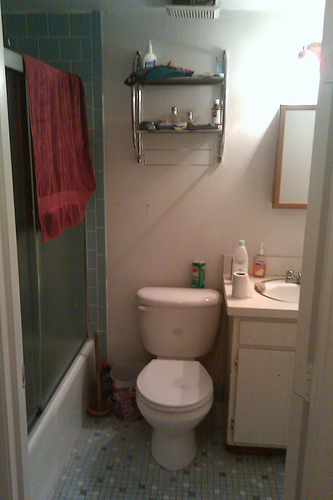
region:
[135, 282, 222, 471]
a white porcelain toilet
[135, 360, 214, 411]
a white plastic toilet seat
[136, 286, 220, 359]
a white porcelain toilet tank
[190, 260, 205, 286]
a can of Comet cleanser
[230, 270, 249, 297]
a roll of toilet paper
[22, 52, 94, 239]
a red bath towel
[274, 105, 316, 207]
a wood framed bathroom mirror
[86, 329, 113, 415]
a toilet plunger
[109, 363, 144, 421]
a bathroom waste basket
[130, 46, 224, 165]
a chrome metal shelf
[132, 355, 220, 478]
This is a toilet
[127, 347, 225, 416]
This is a toilet seat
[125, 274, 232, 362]
This is a toilet cistern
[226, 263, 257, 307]
This is a toilet paper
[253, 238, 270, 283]
This is a toilet hand wash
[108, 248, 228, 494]
This is a toilet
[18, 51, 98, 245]
red towel hanging on the shower door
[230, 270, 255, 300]
roll of toilet paper on the counter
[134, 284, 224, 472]
a white toilet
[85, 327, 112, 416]
a toilet plunger on the floor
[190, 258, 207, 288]
bottle of Comet on the back of the toilet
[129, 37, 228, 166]
set of metal shelves on the wall above the toilet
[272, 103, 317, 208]
corner of a mirror with a wood frame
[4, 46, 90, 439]
frosted glass shower door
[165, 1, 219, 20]
air conditioning vent on the ceiling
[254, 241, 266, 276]
bottle of hand soap by the sink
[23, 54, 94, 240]
a red towel on the shower door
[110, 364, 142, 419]
small round trash can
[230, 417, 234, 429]
hinge on the cabinet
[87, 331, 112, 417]
the plunger has a wooden handle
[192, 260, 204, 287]
green can of cleaning product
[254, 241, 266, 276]
bottle of hand soap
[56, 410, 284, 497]
blue tiles are square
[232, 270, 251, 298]
used roll of toilet paper on the counter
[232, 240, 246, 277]
a bottle of shampoo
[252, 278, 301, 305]
a metal lined sink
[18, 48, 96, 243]
a maroon towel hanging on shower door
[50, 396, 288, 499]
floor made of small square tiles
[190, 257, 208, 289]
a container of comet cleaner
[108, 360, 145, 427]
an oval shaped garbage can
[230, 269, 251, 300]
a used roll of toilet paper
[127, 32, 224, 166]
a silver metal shelf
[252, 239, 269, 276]
bottle of dial hand soap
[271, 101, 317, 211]
a mirror with wood frame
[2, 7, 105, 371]
light green tile for the shower walls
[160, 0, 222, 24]
a hanging vent